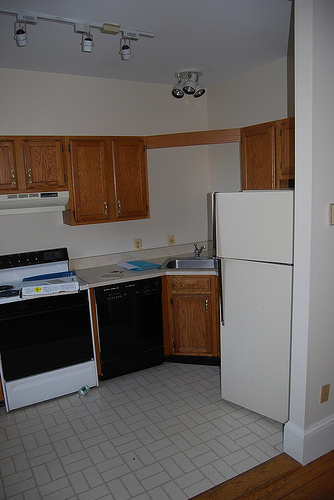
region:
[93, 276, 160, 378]
A black dishwasher.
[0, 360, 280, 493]
Light colored tiles on the floor of the kitchen.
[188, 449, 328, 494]
Hardwood floors.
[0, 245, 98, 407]
A black and white stove.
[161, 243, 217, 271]
A silver sink.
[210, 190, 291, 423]
A white refrigerator.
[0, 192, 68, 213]
A white exhaust fan over a stove.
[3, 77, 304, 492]
A kitchen in a house.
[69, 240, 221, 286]
Beige colored countertops.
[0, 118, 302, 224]
Wooden cabinets above the countertops.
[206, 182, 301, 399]
this is a fridge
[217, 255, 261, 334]
the fridge is closed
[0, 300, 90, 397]
this is an oven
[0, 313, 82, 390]
the oven is closed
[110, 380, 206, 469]
the floor is tiled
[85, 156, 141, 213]
the shelf is closed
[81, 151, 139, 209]
the shelf is wooden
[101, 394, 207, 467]
the floor is white in color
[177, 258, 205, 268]
this is a sink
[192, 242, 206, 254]
this is the tap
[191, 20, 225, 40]
this is the wall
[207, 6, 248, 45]
the wall is white in color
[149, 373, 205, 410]
this is the floor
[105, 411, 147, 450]
the floor is made of tiles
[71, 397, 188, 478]
the tiles are white in color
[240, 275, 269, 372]
the fridge is white in color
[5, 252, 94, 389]
this is a gas cooker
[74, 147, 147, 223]
these are some cupboards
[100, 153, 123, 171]
the cupboards are brown in color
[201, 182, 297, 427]
this is a refrigerator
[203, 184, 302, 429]
the fridge is white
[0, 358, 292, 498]
this is the kitchen floor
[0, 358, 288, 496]
the floor is covered in linoleum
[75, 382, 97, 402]
this is a bottle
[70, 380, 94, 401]
the bottle is on the floor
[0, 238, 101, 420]
this is the oven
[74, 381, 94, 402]
the bottle is plastic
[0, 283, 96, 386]
the door of the oven is black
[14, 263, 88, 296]
this is a cardboard pizza box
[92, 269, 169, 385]
a black dish washer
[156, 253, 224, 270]
a silver kitchen sink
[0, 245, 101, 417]
a white and black oven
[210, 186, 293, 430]
a refrigerator in the kitchen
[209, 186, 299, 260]
the freezer door of the refrigerator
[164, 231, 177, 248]
a light switch above the sink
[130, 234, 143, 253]
an outlet above the dish washer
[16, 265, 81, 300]
a box on top of the stove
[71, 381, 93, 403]
a water bottle in front of the stove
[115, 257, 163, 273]
a blue book above the dishwasher